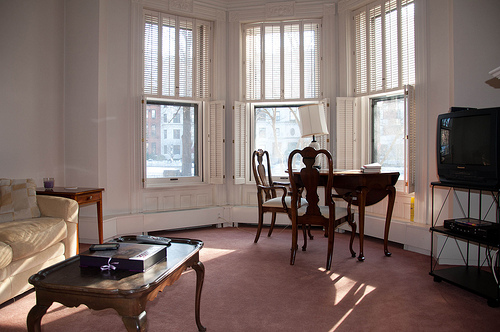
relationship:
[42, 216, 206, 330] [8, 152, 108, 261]
table by couch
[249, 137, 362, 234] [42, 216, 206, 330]
chairs by table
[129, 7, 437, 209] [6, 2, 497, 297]
window in room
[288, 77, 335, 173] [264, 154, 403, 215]
lamp on table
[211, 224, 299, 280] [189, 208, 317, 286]
carpet on floor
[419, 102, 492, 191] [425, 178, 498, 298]
tv on stand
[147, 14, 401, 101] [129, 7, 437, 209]
shutters by window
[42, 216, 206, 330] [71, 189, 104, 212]
table has drawer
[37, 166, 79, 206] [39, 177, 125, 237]
candle on table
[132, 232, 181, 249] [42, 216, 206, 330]
remote on table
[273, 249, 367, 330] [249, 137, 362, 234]
shadows of chairs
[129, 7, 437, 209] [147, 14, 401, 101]
window has shutters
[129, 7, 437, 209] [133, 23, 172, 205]
windows have edges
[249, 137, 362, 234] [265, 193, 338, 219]
chairs has seats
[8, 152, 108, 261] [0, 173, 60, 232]
couch has pillows